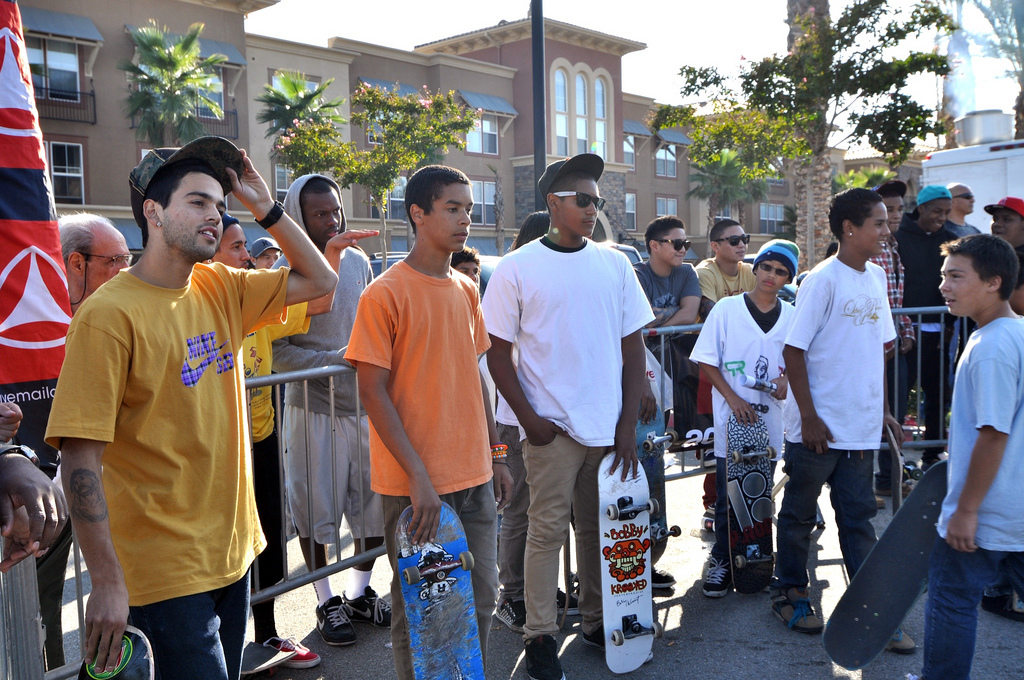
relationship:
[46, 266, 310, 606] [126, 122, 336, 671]
shirt on man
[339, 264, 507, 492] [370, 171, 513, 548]
shirt on boy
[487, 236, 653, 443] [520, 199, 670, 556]
shirt on boy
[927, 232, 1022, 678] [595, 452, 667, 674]
boy with board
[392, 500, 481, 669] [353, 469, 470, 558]
skateboar in hand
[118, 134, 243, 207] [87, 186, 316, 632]
hat on man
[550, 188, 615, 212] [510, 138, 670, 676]
sunglasses on man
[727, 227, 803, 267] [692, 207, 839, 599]
hat on man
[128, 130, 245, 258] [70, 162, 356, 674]
head on man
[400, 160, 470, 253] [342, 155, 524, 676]
head on man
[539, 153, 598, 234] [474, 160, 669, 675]
head on man